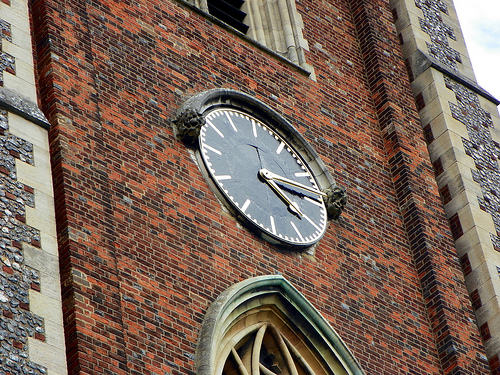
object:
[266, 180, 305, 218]
small hand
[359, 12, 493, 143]
wall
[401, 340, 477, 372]
bricks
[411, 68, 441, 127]
ground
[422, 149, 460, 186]
ground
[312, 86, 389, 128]
brick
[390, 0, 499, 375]
pillar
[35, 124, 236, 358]
bricks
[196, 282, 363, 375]
entrance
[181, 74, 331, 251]
dashes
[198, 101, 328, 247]
clock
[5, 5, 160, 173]
bricks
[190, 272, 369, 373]
arched window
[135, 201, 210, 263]
bricks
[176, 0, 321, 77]
window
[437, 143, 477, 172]
brick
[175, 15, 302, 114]
wall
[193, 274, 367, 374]
archway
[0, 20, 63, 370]
wall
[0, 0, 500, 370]
building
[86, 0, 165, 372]
wall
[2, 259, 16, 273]
bricks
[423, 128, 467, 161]
brick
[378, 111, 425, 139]
brick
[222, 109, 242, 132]
time indicator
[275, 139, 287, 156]
time indicator